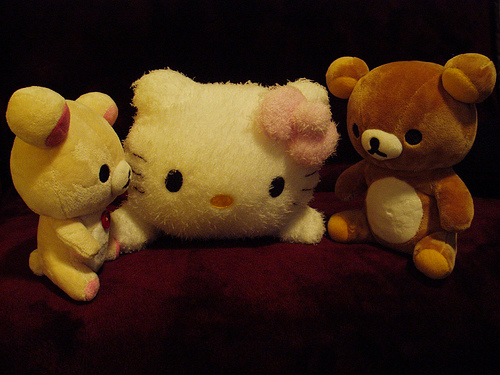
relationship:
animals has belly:
[319, 49, 494, 268] [360, 169, 443, 263]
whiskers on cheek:
[118, 142, 148, 182] [110, 117, 177, 231]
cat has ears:
[113, 68, 340, 249] [132, 52, 225, 113]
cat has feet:
[113, 68, 340, 249] [266, 192, 320, 253]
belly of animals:
[360, 169, 443, 263] [319, 49, 494, 268]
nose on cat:
[202, 189, 255, 215] [113, 55, 327, 262]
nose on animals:
[363, 131, 396, 168] [319, 49, 494, 268]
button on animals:
[100, 210, 113, 230] [319, 49, 494, 268]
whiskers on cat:
[118, 142, 148, 182] [113, 68, 340, 249]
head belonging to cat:
[125, 79, 322, 239] [113, 68, 340, 249]